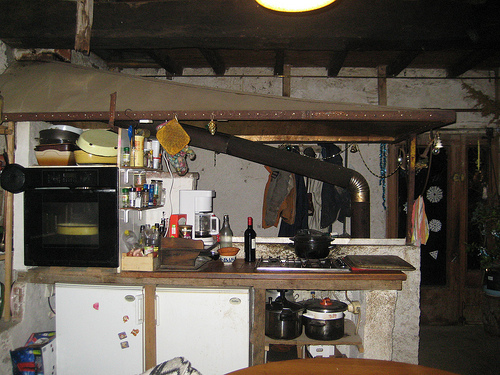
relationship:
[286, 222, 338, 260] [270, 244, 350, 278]
pot on burner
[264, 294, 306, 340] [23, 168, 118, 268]
pots on top of black oven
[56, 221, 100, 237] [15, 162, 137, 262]
pan in oven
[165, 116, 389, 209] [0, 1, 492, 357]
pipe in kitchen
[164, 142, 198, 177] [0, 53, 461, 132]
glove hanging from canopy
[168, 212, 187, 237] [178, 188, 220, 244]
box near coffee maker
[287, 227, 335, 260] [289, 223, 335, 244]
pot with black lid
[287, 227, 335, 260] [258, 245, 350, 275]
pot on stovetop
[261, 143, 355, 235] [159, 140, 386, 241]
coats on wall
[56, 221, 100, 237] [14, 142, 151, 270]
pan in oven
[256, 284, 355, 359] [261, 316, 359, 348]
pots on shelf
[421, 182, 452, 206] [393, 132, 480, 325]
snowflake on door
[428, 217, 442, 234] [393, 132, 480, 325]
snowflake on door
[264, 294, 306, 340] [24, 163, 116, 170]
pots on shelf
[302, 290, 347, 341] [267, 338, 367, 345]
pots on shelf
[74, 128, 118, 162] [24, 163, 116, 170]
pots on shelf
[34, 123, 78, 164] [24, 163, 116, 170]
pots on shelf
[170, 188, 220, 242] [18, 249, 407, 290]
coffee maker on counter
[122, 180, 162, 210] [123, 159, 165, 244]
spices on shelf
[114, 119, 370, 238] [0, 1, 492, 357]
pipe going through kitchen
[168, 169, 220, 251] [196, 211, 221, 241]
coffee maker with pot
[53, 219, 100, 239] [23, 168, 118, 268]
pan inside black oven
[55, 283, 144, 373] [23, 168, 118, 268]
fridge under black oven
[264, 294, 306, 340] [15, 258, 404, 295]
pots under counter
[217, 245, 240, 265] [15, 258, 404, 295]
bowl on counter